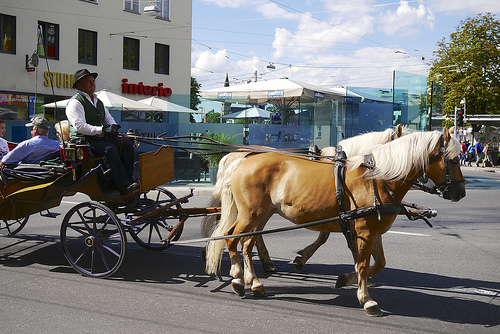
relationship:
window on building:
[122, 35, 141, 75] [9, 83, 198, 187]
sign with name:
[42, 70, 78, 88] [43, 67, 76, 89]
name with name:
[121, 78, 174, 96] [121, 75, 174, 96]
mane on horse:
[329, 119, 440, 186] [228, 128, 435, 268]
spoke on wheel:
[61, 206, 153, 291] [76, 145, 186, 239]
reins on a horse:
[109, 122, 346, 164] [205, 124, 467, 283]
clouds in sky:
[191, 1, 498, 103] [190, 0, 499, 91]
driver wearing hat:
[65, 68, 139, 193] [70, 62, 102, 84]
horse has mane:
[229, 156, 398, 253] [356, 139, 430, 177]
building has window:
[2, 1, 196, 168] [2, 13, 18, 55]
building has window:
[2, 1, 196, 168] [37, 18, 61, 60]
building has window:
[2, 1, 196, 168] [77, 27, 99, 66]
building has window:
[2, 1, 196, 168] [120, 33, 142, 71]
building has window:
[2, 1, 196, 168] [154, 41, 171, 76]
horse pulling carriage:
[205, 124, 467, 283] [2, 142, 440, 279]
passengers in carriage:
[0, 117, 61, 165] [2, 142, 440, 279]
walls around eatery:
[0, 69, 420, 182] [9, 10, 191, 160]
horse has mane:
[205, 124, 467, 283] [347, 128, 464, 180]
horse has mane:
[312, 116, 417, 160] [332, 121, 413, 156]